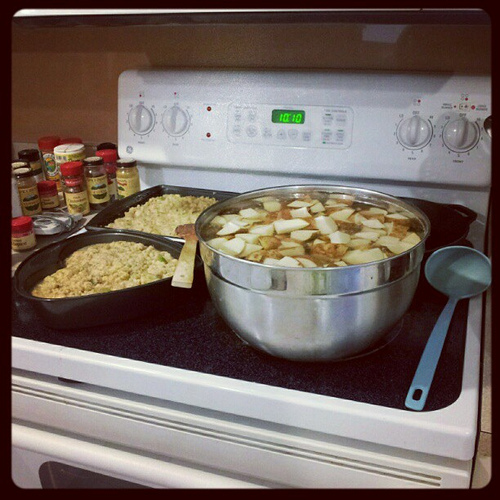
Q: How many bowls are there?
A: One.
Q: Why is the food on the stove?
A: It's being cooked.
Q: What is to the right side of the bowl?
A: A ladle.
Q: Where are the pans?
A: On the stove.